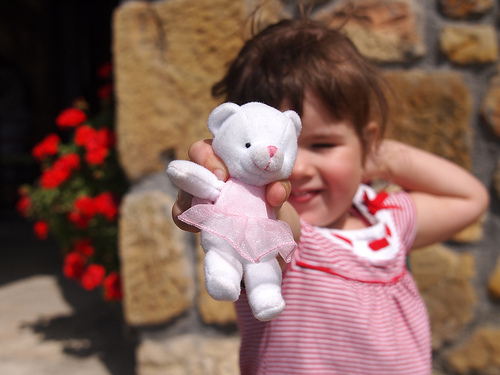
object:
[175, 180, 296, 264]
skirt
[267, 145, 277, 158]
pink nose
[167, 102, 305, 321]
bear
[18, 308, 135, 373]
shadow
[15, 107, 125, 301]
flowers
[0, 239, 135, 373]
ground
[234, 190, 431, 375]
shirt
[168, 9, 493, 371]
girl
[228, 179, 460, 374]
dress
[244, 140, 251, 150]
eye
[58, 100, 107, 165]
flower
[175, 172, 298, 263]
tutu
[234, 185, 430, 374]
dress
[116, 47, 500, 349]
wall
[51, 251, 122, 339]
pot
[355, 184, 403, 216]
bow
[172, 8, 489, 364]
girl